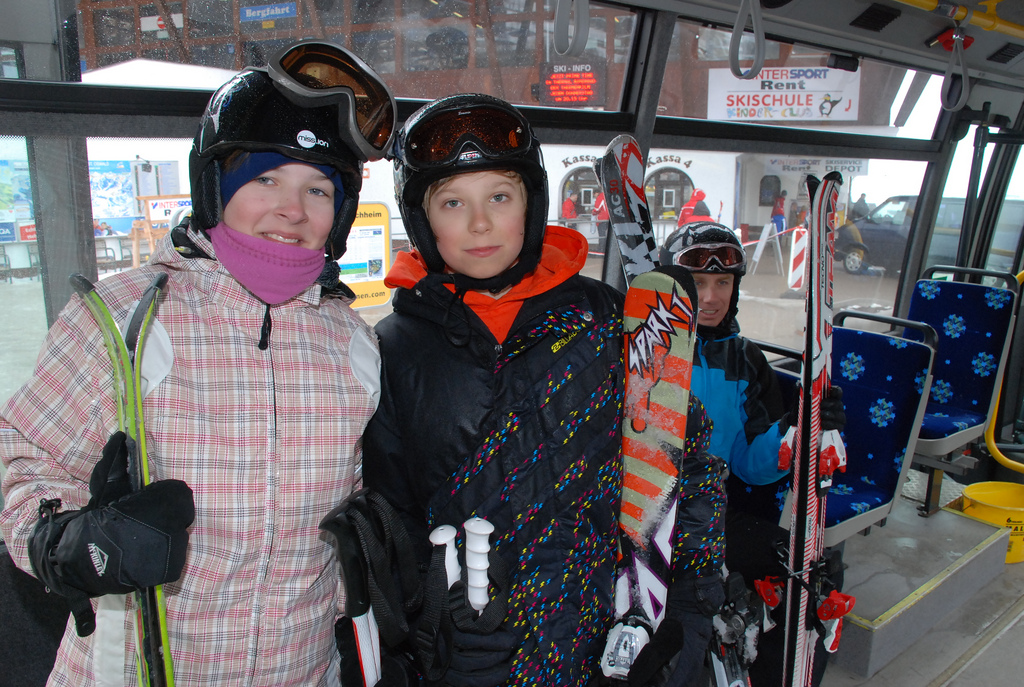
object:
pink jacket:
[0, 225, 381, 687]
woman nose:
[468, 201, 493, 235]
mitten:
[28, 431, 194, 637]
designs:
[840, 331, 928, 427]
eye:
[254, 176, 278, 185]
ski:
[617, 265, 699, 682]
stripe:
[624, 389, 686, 439]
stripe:
[624, 287, 694, 332]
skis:
[754, 171, 844, 686]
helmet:
[660, 221, 748, 332]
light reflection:
[668, 222, 730, 252]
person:
[362, 92, 730, 687]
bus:
[0, 0, 1024, 687]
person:
[660, 221, 856, 687]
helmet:
[393, 93, 548, 292]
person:
[0, 39, 400, 687]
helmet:
[187, 40, 396, 260]